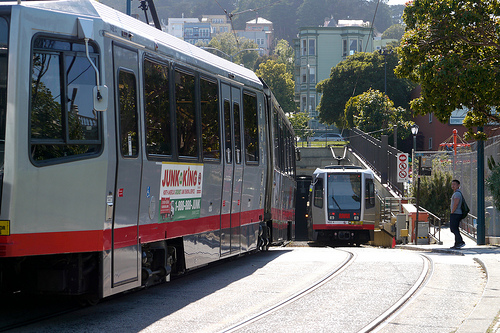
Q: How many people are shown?
A: One.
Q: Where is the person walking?
A: Sidewalk.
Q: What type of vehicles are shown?
A: Trains.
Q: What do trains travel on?
A: Tracks.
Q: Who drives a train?
A: Conductor.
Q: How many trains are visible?
A: Two.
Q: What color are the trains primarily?
A: Gray.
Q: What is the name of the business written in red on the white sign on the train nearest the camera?
A: Junk King.